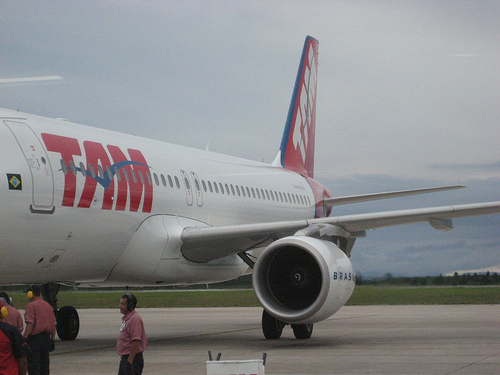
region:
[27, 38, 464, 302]
airplane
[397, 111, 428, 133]
white clouds in blue sky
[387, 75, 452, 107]
white clouds in blue sky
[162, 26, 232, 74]
white clouds in blue sky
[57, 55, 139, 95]
white clouds in blue sky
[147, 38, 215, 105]
white clouds in blue sky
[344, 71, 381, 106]
white clouds in blue sky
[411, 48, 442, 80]
white clouds in blue sky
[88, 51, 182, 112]
white clouds in blue sky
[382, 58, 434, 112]
white clouds in blue sky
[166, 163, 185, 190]
window on side of airplane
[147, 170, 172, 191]
window on side of airplane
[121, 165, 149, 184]
window on side of airplane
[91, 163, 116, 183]
window on side of airplane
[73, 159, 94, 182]
window on side of airplane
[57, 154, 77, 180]
window on side of airplane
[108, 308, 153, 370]
man wearing a pink shirt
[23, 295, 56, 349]
man wearing a pink shirt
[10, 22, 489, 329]
white airplane with red tail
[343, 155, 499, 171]
hazy clouds in the sky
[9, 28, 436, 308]
red and white plane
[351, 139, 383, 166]
white clouds in blue sky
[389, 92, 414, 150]
white clouds in blue sky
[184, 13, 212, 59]
white clouds in blue sky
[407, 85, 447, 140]
white clouds in blue sky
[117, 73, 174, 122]
white clouds in blue sky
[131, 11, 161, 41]
white clouds in blue sky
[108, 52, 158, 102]
white clouds in blue sky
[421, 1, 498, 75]
white clouds in blue sky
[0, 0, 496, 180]
The sky appears to be overcast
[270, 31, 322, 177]
The tail of a plane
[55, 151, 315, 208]
Many windows on side of a plane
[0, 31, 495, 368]
A large airplane on the runway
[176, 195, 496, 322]
The wing of a plane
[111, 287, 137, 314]
A man is wearing headphones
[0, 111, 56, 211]
A door on the airplane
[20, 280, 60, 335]
Man wearing a pink shirt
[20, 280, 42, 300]
The headphones are yellow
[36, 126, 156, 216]
"TAM" is written in red letters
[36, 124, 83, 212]
red letter t on plane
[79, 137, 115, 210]
red letter A on plane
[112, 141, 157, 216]
red letter m on plane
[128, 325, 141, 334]
man wearing peach shirt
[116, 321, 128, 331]
white tag on shirt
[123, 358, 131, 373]
black gloves on hand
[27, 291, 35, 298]
yellow ear muffs on man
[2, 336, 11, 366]
man wearing red shirt